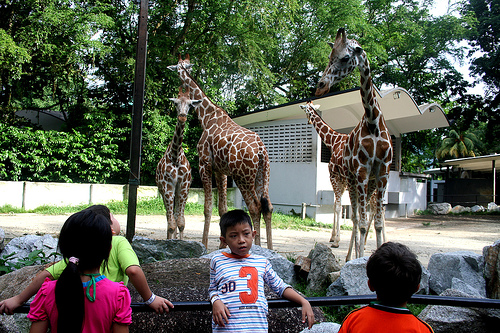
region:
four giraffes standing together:
[145, 34, 396, 241]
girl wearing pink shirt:
[21, 215, 128, 331]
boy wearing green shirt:
[29, 216, 164, 320]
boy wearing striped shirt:
[207, 214, 291, 331]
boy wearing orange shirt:
[332, 235, 429, 331]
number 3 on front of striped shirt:
[235, 264, 262, 304]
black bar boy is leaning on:
[7, 280, 492, 310]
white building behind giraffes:
[225, 80, 432, 207]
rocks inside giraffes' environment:
[7, 238, 492, 304]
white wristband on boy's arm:
[202, 290, 220, 304]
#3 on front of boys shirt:
[235, 262, 262, 309]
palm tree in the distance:
[437, 105, 479, 157]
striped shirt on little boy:
[198, 209, 308, 328]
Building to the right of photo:
[422, 149, 494, 226]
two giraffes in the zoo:
[299, 33, 434, 236]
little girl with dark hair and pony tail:
[43, 190, 127, 330]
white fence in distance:
[4, 162, 131, 209]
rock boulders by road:
[432, 242, 494, 290]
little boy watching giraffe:
[338, 213, 425, 329]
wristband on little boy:
[144, 292, 161, 304]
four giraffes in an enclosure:
[153, 28, 394, 262]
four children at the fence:
[3, 203, 435, 332]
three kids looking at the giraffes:
[0, 203, 434, 330]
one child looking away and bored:
[203, 208, 316, 332]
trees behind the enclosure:
[3, 1, 498, 186]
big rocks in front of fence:
[1, 232, 498, 332]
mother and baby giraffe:
[155, 51, 273, 247]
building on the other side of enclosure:
[231, 80, 492, 220]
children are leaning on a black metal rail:
[1, 291, 496, 306]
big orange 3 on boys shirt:
[235, 263, 261, 304]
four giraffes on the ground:
[128, 28, 403, 235]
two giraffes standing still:
[295, 6, 405, 254]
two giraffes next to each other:
[128, 43, 274, 248]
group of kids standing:
[47, 193, 468, 331]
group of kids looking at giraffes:
[43, 216, 421, 331]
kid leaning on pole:
[180, 214, 299, 331]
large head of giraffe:
[298, 25, 365, 98]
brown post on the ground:
[113, 13, 159, 233]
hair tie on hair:
[68, 255, 78, 270]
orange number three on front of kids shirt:
[237, 261, 259, 310]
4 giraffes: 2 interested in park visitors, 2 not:
[151, 18, 399, 263]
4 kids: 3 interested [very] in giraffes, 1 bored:
[1, 195, 441, 330]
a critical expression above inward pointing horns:
[305, 22, 365, 104]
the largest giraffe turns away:
[164, 53, 282, 264]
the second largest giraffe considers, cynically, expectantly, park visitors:
[308, 23, 406, 259]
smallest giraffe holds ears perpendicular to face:
[148, 83, 206, 239]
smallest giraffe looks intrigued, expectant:
[163, 82, 201, 124]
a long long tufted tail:
[252, 137, 279, 222]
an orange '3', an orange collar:
[213, 245, 265, 307]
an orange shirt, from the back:
[323, 303, 442, 332]